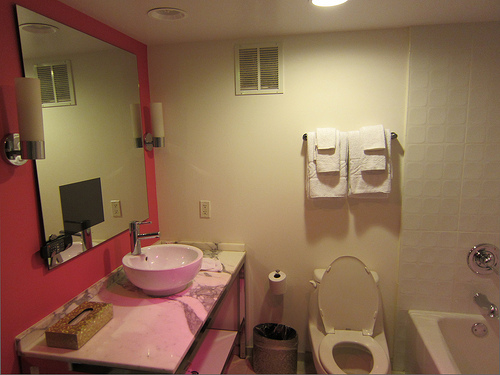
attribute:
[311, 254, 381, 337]
seat — up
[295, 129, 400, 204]
towels — white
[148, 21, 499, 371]
wall — red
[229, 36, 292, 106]
vent — white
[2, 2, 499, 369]
bathroom — white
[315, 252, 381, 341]
lid — up